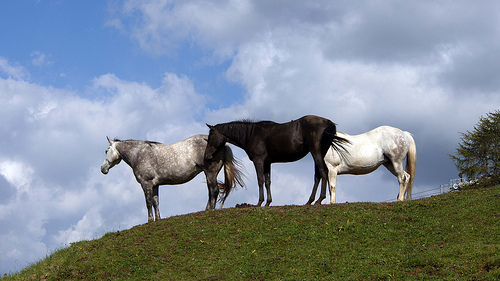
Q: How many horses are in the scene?
A: Three.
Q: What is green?
A: Grass.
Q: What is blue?
A: Sky.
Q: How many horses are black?
A: One.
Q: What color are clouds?
A: White.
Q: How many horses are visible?
A: Three.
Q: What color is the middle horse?
A: Black.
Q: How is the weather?
A: Cloudy.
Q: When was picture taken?
A: During the daytime.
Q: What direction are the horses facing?
A: To the left.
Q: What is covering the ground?
A: Grass.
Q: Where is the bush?
A: On the right.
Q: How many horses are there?
A: Three.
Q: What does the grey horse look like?
A: Bulky.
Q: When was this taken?
A: This morning.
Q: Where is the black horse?
A: Between the grey and white horses.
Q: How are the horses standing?
A: Facing the left.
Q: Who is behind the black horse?
A: White horse.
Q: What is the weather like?
A: Cloudy.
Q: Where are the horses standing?
A: On a hill.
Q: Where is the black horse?
A: In the middle.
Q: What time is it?
A: Afternoon.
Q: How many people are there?
A: None.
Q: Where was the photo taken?
A: Outdoors somewhere.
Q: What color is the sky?
A: Blue.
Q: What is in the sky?
A: Clouds.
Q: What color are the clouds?
A: White.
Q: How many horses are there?
A: Three.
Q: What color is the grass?
A: Green.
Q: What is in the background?
A: Trees.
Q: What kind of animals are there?
A: Horses.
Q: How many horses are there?
A: 3.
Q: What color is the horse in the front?
A: Grey.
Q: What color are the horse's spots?
A: White.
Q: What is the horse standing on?
A: A grassy hill.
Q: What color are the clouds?
A: White.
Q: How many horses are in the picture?
A: Three.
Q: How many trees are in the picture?
A: One.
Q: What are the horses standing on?
A: Grass.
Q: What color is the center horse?
A: Black.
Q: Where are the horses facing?
A: Left.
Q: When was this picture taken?
A: During the day.